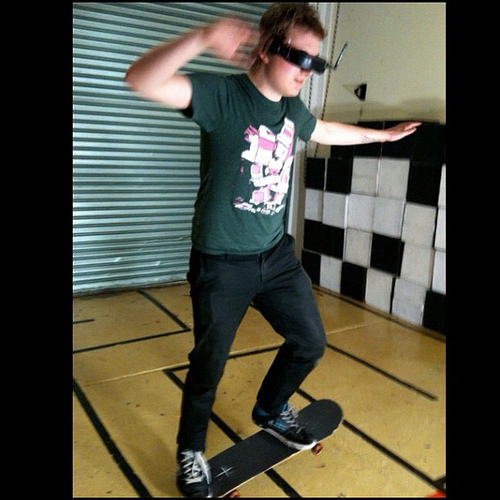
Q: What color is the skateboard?
A: Black.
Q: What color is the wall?
A: White.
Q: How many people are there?
A: One.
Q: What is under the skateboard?
A: The floor.